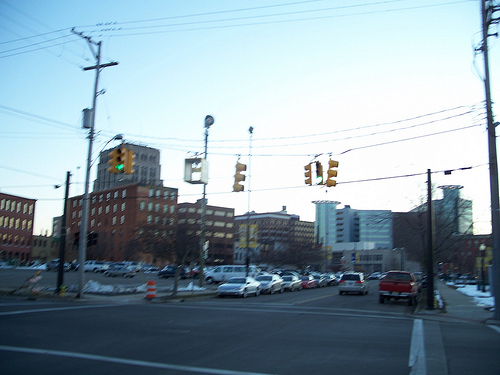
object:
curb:
[417, 274, 430, 312]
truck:
[376, 270, 424, 307]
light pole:
[197, 110, 216, 290]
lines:
[173, 295, 429, 374]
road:
[0, 279, 499, 374]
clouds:
[225, 44, 394, 131]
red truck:
[377, 271, 420, 303]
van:
[206, 262, 258, 285]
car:
[335, 270, 368, 297]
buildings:
[66, 142, 330, 275]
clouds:
[0, 0, 498, 218]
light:
[108, 146, 133, 175]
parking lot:
[0, 261, 315, 298]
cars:
[98, 262, 137, 279]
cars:
[83, 257, 110, 275]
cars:
[158, 262, 199, 279]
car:
[217, 275, 257, 297]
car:
[257, 271, 282, 294]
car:
[280, 273, 297, 291]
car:
[299, 271, 313, 289]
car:
[316, 271, 330, 286]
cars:
[213, 269, 371, 298]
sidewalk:
[0, 266, 227, 302]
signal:
[233, 164, 249, 192]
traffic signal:
[233, 162, 249, 193]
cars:
[104, 259, 201, 281]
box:
[80, 107, 95, 128]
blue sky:
[0, 0, 499, 234]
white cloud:
[218, 83, 420, 123]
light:
[302, 162, 314, 187]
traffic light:
[106, 147, 137, 176]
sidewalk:
[410, 282, 499, 326]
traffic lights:
[107, 146, 338, 193]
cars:
[215, 267, 333, 298]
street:
[0, 279, 499, 374]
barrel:
[146, 278, 157, 300]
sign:
[233, 224, 259, 248]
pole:
[70, 25, 120, 300]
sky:
[0, 0, 499, 236]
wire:
[91, 120, 486, 161]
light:
[324, 158, 341, 188]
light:
[315, 159, 322, 186]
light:
[232, 163, 248, 194]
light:
[118, 147, 138, 176]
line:
[168, 294, 424, 316]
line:
[143, 299, 413, 319]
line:
[3, 341, 280, 374]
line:
[407, 313, 424, 371]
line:
[0, 299, 131, 316]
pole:
[245, 220, 248, 281]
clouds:
[12, 98, 80, 159]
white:
[6, 114, 61, 151]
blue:
[12, 15, 52, 51]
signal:
[326, 155, 339, 186]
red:
[377, 270, 414, 293]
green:
[117, 163, 123, 170]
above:
[105, 145, 139, 173]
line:
[237, 300, 392, 317]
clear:
[172, 66, 373, 161]